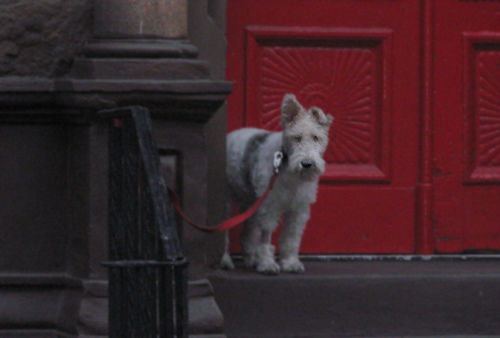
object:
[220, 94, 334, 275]
dog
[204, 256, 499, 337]
stoop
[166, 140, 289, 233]
leash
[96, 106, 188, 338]
handrail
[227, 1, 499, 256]
doors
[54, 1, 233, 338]
post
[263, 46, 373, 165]
design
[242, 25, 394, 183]
frame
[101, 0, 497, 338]
building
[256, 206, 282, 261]
leg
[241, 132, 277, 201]
strip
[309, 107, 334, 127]
ear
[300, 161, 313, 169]
nose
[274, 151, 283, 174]
clasp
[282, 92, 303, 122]
one ear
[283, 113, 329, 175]
face